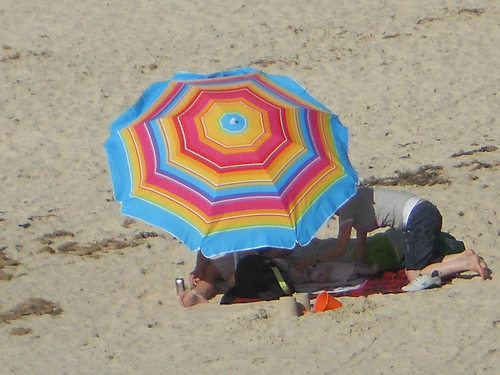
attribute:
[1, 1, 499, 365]
ground — tan, brown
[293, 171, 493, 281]
person — under, white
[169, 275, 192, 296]
can — silver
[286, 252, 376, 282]
baby — small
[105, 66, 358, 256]
umbrella — red, colorful, rainbow, wide, yellow, pink, blue, multicolored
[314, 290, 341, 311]
bucket — orange